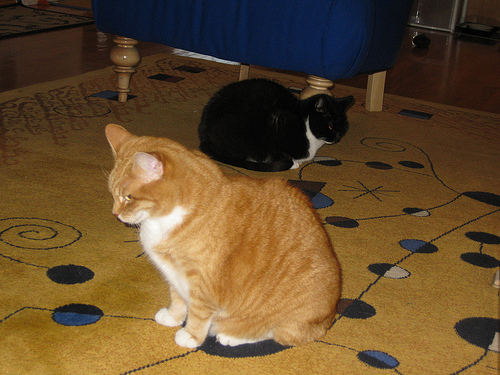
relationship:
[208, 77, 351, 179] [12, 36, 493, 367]
cat on floor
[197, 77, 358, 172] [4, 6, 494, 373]
cat on floor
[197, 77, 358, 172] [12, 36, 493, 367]
cat on floor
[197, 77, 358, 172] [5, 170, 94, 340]
cat sitting floor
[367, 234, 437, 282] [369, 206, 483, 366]
patterns on carpet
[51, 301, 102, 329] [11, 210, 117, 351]
circle woven carpet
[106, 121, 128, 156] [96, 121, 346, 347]
ear of cat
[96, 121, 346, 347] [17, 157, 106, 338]
cat sitting floor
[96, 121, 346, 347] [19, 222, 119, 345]
cat sitting carpet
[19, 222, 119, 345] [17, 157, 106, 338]
carpet on floor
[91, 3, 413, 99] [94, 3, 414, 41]
cushion on couch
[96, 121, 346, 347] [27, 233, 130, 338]
cat on rug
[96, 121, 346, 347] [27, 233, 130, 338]
cat sitting rug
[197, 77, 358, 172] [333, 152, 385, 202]
cat laying rug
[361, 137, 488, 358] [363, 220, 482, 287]
rug with pattern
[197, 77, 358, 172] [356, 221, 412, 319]
cat sitting rug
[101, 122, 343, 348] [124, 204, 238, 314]
cat with chest